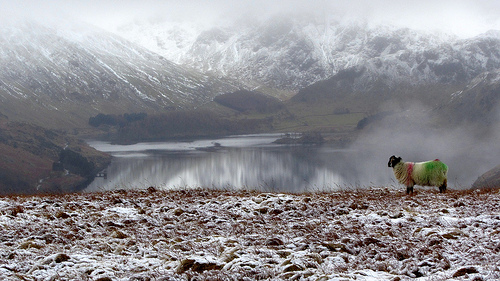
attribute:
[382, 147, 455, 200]
animal — colored, multi-colored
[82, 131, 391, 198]
lake — calm, frozen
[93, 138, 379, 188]
water — small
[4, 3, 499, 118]
mountains — brown, rough, green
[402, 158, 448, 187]
red, white and green — red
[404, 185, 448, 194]
legs — black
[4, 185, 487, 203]
grass — brown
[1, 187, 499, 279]
ground — brown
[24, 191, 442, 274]
grass — dried